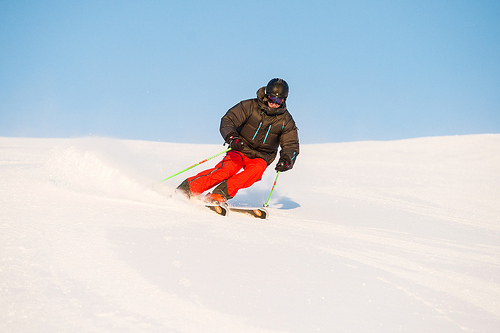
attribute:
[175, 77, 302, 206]
man — skiing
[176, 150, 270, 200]
pants — red, orange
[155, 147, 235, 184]
pole — green, yellow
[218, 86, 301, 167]
jacket — puffy, black, brown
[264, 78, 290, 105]
helmet — black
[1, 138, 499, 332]
snow — white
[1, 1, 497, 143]
sky — blue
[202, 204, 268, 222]
skis — black, blue, kicking, long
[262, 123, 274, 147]
zipper — blue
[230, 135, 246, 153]
glove — black